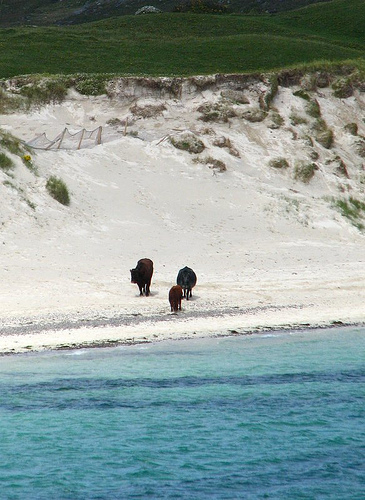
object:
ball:
[23, 153, 31, 161]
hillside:
[0, 74, 365, 357]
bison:
[169, 285, 184, 314]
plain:
[0, 0, 365, 87]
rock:
[183, 92, 365, 183]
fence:
[21, 104, 180, 150]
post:
[24, 131, 45, 146]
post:
[56, 118, 66, 151]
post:
[98, 126, 103, 144]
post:
[78, 128, 85, 151]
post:
[124, 117, 128, 136]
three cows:
[130, 259, 198, 312]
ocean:
[0, 324, 364, 498]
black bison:
[176, 266, 197, 300]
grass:
[0, 2, 363, 237]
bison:
[130, 257, 154, 296]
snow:
[0, 61, 365, 354]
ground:
[1, 0, 362, 354]